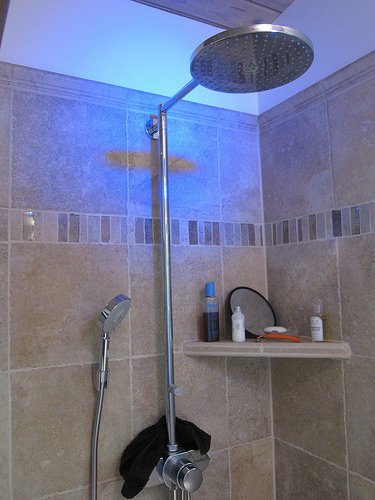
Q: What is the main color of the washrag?
A: Green.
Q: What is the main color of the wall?
A: White.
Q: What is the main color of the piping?
A: Gray.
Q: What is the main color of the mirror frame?
A: Black.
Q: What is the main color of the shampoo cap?
A: Blue.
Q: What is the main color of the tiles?
A: Brown.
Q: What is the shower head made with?
A: Metal.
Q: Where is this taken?
A: A bathroom.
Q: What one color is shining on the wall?
A: Blue.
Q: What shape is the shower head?
A: Circle.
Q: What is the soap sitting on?
A: A shelf.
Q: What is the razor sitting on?
A: A shelf.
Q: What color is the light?
A: Blue.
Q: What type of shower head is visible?
A: Stainless steel.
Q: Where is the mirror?
A: On a shelf.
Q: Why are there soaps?
A: To get clean.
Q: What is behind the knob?
A: A towel.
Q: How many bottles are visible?
A: 3.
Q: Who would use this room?
A: Someone needing a shower.